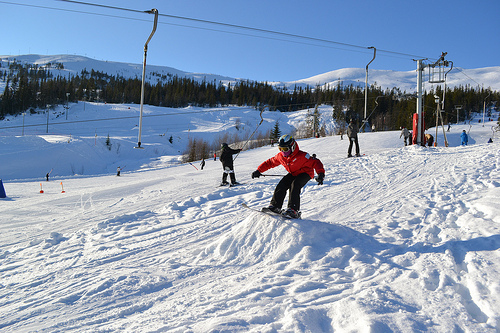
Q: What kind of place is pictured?
A: It is a park.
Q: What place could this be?
A: It is a park.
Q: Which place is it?
A: It is a park.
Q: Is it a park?
A: Yes, it is a park.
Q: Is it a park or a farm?
A: It is a park.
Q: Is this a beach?
A: No, it is a park.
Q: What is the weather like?
A: It is clear.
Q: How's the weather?
A: It is clear.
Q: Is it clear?
A: Yes, it is clear.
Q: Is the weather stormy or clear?
A: It is clear.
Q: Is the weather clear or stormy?
A: It is clear.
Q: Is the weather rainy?
A: No, it is clear.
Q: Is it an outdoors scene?
A: Yes, it is outdoors.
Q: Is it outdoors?
A: Yes, it is outdoors.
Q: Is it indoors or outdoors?
A: It is outdoors.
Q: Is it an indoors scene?
A: No, it is outdoors.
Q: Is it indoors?
A: No, it is outdoors.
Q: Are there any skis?
A: Yes, there are skis.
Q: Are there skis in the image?
A: Yes, there are skis.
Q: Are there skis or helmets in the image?
A: Yes, there are skis.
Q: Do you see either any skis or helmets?
A: Yes, there are skis.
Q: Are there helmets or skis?
A: Yes, there are skis.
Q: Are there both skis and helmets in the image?
A: Yes, there are both skis and a helmet.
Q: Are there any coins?
A: No, there are no coins.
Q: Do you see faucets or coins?
A: No, there are no coins or faucets.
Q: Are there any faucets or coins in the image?
A: No, there are no coins or faucets.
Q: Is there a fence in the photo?
A: No, there are no fences.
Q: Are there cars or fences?
A: No, there are no fences or cars.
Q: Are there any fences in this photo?
A: No, there are no fences.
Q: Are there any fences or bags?
A: No, there are no fences or bags.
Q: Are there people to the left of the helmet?
A: Yes, there is a person to the left of the helmet.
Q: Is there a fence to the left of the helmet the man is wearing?
A: No, there is a person to the left of the helmet.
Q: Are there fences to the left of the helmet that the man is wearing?
A: No, there is a person to the left of the helmet.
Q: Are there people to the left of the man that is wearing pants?
A: Yes, there is a person to the left of the man.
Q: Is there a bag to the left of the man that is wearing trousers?
A: No, there is a person to the left of the man.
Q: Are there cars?
A: No, there are no cars.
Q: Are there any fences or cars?
A: No, there are no cars or fences.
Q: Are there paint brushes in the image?
A: No, there are no paint brushes.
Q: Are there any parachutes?
A: No, there are no parachutes.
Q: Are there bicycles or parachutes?
A: No, there are no parachutes or bicycles.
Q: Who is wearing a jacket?
A: The man is wearing a jacket.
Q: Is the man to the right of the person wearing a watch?
A: No, the man is wearing a jacket.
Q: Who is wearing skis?
A: The man is wearing skis.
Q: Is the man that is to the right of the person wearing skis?
A: Yes, the man is wearing skis.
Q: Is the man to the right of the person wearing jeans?
A: No, the man is wearing skis.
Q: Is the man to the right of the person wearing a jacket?
A: Yes, the man is wearing a jacket.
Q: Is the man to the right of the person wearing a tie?
A: No, the man is wearing a jacket.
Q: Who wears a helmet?
A: The man wears a helmet.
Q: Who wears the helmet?
A: The man wears a helmet.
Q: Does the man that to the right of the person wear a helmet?
A: Yes, the man wears a helmet.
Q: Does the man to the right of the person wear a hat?
A: No, the man wears a helmet.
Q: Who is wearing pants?
A: The man is wearing pants.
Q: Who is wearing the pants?
A: The man is wearing pants.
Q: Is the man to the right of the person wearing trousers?
A: Yes, the man is wearing trousers.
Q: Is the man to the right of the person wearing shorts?
A: No, the man is wearing trousers.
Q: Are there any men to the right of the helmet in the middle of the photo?
A: Yes, there is a man to the right of the helmet.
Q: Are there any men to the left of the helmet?
A: No, the man is to the right of the helmet.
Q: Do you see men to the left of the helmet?
A: No, the man is to the right of the helmet.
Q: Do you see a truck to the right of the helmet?
A: No, there is a man to the right of the helmet.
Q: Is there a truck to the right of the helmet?
A: No, there is a man to the right of the helmet.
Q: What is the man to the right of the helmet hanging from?
A: The man is hanging from the pole.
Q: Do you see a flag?
A: No, there are no flags.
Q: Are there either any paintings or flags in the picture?
A: No, there are no flags or paintings.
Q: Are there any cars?
A: No, there are no cars.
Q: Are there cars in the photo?
A: No, there are no cars.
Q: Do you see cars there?
A: No, there are no cars.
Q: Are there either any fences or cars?
A: No, there are no cars or fences.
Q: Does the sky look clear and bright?
A: Yes, the sky is clear and bright.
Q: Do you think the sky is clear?
A: Yes, the sky is clear.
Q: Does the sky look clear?
A: Yes, the sky is clear.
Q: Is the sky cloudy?
A: No, the sky is clear.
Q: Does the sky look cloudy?
A: No, the sky is clear.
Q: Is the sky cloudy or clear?
A: The sky is clear.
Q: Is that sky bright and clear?
A: Yes, the sky is bright and clear.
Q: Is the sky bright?
A: Yes, the sky is bright.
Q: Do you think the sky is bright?
A: Yes, the sky is bright.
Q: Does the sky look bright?
A: Yes, the sky is bright.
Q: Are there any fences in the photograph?
A: No, there are no fences.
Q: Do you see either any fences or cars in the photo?
A: No, there are no fences or cars.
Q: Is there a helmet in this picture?
A: Yes, there is a helmet.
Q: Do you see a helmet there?
A: Yes, there is a helmet.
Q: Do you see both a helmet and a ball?
A: No, there is a helmet but no balls.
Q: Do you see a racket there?
A: No, there are no rackets.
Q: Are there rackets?
A: No, there are no rackets.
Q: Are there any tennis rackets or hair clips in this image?
A: No, there are no tennis rackets or hair clips.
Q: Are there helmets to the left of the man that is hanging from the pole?
A: Yes, there is a helmet to the left of the man.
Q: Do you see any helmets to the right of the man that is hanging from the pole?
A: No, the helmet is to the left of the man.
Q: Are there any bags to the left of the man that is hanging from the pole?
A: No, there is a helmet to the left of the man.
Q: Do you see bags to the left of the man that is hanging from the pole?
A: No, there is a helmet to the left of the man.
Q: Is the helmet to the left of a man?
A: Yes, the helmet is to the left of a man.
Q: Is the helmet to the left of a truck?
A: No, the helmet is to the left of a man.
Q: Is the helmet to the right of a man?
A: No, the helmet is to the left of a man.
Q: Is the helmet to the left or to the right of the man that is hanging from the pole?
A: The helmet is to the left of the man.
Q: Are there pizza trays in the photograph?
A: No, there are no pizza trays.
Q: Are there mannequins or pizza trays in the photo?
A: No, there are no pizza trays or mannequins.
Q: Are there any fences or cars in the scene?
A: No, there are no cars or fences.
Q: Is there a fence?
A: No, there are no fences.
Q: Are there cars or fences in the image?
A: No, there are no fences or cars.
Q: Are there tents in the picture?
A: No, there are no tents.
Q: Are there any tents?
A: No, there are no tents.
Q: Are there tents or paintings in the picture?
A: No, there are no tents or paintings.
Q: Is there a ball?
A: No, there are no balls.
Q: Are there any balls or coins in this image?
A: No, there are no balls or coins.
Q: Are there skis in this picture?
A: Yes, there are skis.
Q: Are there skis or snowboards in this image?
A: Yes, there are skis.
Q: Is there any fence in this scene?
A: No, there are no fences.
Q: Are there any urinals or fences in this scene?
A: No, there are no fences or urinals.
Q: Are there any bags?
A: No, there are no bags.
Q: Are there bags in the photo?
A: No, there are no bags.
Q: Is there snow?
A: Yes, there is snow.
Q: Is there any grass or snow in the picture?
A: Yes, there is snow.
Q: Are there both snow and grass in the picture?
A: No, there is snow but no grass.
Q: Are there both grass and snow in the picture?
A: No, there is snow but no grass.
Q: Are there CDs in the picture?
A: No, there are no cds.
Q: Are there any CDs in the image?
A: No, there are no cds.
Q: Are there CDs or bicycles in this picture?
A: No, there are no CDs or bicycles.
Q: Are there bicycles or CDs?
A: No, there are no CDs or bicycles.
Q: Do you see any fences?
A: No, there are no fences.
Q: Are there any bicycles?
A: No, there are no bicycles.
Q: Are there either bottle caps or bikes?
A: No, there are no bikes or bottle caps.